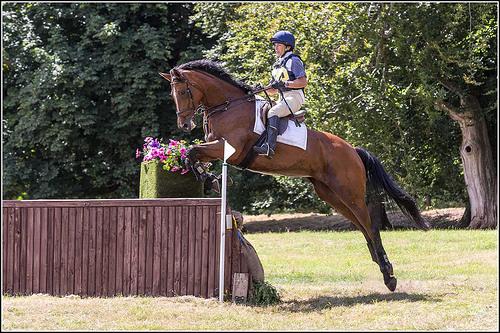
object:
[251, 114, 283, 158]
boots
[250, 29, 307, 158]
person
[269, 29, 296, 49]
helmet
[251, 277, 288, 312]
weeds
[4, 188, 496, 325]
ground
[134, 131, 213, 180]
flowers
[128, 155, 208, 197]
box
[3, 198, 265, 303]
fence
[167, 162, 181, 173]
flower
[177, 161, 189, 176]
flower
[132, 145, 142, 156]
flower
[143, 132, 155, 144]
flower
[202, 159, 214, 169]
flower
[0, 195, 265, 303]
wooden fence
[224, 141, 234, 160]
white flag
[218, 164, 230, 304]
pole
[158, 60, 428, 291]
horse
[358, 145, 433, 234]
tail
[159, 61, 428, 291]
brown horse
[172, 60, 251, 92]
black mane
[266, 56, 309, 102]
shirt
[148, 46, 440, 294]
horse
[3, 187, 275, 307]
obstacle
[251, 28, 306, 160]
horseback rider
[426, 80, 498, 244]
trunk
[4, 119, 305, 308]
wall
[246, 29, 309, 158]
woman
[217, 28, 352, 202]
someone